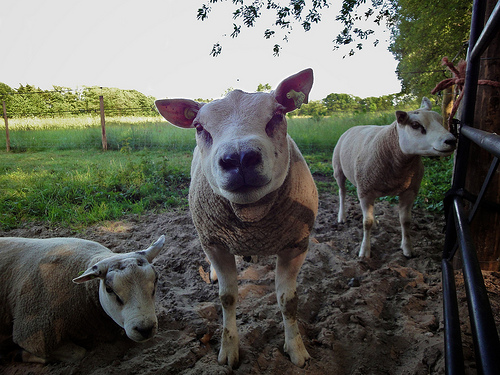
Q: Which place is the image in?
A: It is at the field.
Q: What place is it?
A: It is a field.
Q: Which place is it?
A: It is a field.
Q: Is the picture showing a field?
A: Yes, it is showing a field.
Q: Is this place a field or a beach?
A: It is a field.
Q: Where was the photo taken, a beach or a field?
A: It was taken at a field.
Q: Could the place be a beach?
A: No, it is a field.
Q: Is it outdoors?
A: Yes, it is outdoors.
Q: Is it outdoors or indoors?
A: It is outdoors.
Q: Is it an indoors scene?
A: No, it is outdoors.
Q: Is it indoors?
A: No, it is outdoors.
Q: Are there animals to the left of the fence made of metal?
A: Yes, there is an animal to the left of the fence.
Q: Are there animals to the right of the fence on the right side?
A: No, the animal is to the left of the fence.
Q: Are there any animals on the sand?
A: Yes, there is an animal on the sand.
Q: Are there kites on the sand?
A: No, there is an animal on the sand.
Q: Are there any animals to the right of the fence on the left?
A: Yes, there is an animal to the right of the fence.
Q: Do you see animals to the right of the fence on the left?
A: Yes, there is an animal to the right of the fence.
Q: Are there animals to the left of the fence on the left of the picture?
A: No, the animal is to the right of the fence.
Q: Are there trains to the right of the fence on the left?
A: No, there is an animal to the right of the fence.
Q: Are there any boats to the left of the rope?
A: No, there is an animal to the left of the rope.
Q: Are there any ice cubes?
A: No, there are no ice cubes.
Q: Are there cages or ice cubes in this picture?
A: No, there are no ice cubes or cages.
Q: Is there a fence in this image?
A: Yes, there is a fence.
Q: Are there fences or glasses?
A: Yes, there is a fence.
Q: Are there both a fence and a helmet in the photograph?
A: No, there is a fence but no helmets.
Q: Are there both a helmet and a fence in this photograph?
A: No, there is a fence but no helmets.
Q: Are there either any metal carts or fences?
A: Yes, there is a metal fence.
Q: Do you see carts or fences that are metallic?
A: Yes, the fence is metallic.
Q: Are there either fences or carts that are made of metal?
A: Yes, the fence is made of metal.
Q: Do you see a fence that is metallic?
A: Yes, there is a metal fence.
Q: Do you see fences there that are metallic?
A: Yes, there is a fence that is metallic.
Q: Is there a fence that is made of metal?
A: Yes, there is a fence that is made of metal.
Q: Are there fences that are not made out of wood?
A: Yes, there is a fence that is made of metal.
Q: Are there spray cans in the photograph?
A: No, there are no spray cans.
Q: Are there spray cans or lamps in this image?
A: No, there are no spray cans or lamps.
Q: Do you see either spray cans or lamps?
A: No, there are no spray cans or lamps.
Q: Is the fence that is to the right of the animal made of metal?
A: Yes, the fence is made of metal.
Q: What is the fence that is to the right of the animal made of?
A: The fence is made of metal.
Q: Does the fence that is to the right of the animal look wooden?
A: No, the fence is metallic.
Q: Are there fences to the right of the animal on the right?
A: Yes, there is a fence to the right of the animal.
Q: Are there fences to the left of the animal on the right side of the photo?
A: No, the fence is to the right of the animal.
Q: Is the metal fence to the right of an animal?
A: Yes, the fence is to the right of an animal.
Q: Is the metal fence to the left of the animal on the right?
A: No, the fence is to the right of the animal.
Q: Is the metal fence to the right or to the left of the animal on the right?
A: The fence is to the right of the animal.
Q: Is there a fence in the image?
A: Yes, there is a fence.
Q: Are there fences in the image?
A: Yes, there is a fence.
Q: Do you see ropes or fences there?
A: Yes, there is a fence.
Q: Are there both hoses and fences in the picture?
A: No, there is a fence but no hoses.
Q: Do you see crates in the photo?
A: No, there are no crates.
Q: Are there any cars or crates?
A: No, there are no crates or cars.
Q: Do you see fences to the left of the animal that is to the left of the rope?
A: Yes, there is a fence to the left of the animal.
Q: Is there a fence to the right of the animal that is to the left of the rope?
A: No, the fence is to the left of the animal.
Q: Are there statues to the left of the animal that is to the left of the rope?
A: No, there is a fence to the left of the animal.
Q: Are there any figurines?
A: No, there are no figurines.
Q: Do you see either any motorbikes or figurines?
A: No, there are no figurines or motorbikes.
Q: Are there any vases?
A: No, there are no vases.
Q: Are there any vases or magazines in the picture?
A: No, there are no vases or magazines.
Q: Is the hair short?
A: Yes, the hair is short.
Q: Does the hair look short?
A: Yes, the hair is short.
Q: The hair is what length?
A: The hair is short.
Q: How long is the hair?
A: The hair is short.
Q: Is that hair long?
A: No, the hair is short.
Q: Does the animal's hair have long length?
A: No, the hair is short.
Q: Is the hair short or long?
A: The hair is short.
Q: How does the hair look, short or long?
A: The hair is short.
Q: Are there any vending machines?
A: No, there are no vending machines.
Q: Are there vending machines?
A: No, there are no vending machines.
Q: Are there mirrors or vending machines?
A: No, there are no vending machines or mirrors.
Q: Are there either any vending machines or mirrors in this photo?
A: No, there are no vending machines or mirrors.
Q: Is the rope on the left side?
A: No, the rope is on the right of the image.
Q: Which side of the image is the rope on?
A: The rope is on the right of the image.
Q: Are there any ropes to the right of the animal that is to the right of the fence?
A: Yes, there is a rope to the right of the animal.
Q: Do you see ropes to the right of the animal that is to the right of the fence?
A: Yes, there is a rope to the right of the animal.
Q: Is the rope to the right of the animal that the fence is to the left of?
A: Yes, the rope is to the right of the animal.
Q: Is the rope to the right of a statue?
A: No, the rope is to the right of the animal.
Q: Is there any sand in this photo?
A: Yes, there is sand.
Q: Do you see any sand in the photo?
A: Yes, there is sand.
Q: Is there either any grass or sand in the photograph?
A: Yes, there is sand.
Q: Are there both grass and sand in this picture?
A: Yes, there are both sand and grass.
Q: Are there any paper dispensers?
A: No, there are no paper dispensers.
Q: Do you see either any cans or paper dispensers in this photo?
A: No, there are no paper dispensers or cans.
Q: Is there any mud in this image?
A: Yes, there is mud.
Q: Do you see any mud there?
A: Yes, there is mud.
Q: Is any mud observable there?
A: Yes, there is mud.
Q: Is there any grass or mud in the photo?
A: Yes, there is mud.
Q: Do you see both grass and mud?
A: Yes, there are both mud and grass.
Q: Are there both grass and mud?
A: Yes, there are both mud and grass.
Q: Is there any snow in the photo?
A: No, there is no snow.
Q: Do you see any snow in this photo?
A: No, there is no snow.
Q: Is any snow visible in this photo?
A: No, there is no snow.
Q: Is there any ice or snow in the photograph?
A: No, there are no snow or ice.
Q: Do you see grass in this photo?
A: Yes, there is grass.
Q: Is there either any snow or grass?
A: Yes, there is grass.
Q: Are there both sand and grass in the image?
A: Yes, there are both grass and sand.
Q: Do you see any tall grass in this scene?
A: Yes, there is tall grass.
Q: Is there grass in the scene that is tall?
A: Yes, there is grass that is tall.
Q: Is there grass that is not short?
A: Yes, there is tall grass.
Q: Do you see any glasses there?
A: No, there are no glasses.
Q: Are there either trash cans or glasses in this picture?
A: No, there are no glasses or trash cans.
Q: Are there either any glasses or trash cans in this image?
A: No, there are no glasses or trash cans.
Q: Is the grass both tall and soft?
A: Yes, the grass is tall and soft.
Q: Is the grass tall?
A: Yes, the grass is tall.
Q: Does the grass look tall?
A: Yes, the grass is tall.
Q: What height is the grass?
A: The grass is tall.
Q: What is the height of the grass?
A: The grass is tall.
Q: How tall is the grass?
A: The grass is tall.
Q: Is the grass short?
A: No, the grass is tall.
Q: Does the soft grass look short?
A: No, the grass is tall.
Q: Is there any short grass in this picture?
A: No, there is grass but it is tall.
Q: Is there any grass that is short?
A: No, there is grass but it is tall.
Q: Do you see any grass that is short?
A: No, there is grass but it is tall.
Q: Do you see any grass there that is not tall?
A: No, there is grass but it is tall.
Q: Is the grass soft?
A: Yes, the grass is soft.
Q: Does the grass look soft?
A: Yes, the grass is soft.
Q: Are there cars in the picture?
A: No, there are no cars.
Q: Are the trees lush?
A: Yes, the trees are lush.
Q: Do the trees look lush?
A: Yes, the trees are lush.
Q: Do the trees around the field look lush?
A: Yes, the trees are lush.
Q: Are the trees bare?
A: No, the trees are lush.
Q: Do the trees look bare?
A: No, the trees are lush.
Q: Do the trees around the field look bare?
A: No, the trees are lush.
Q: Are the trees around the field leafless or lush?
A: The trees are lush.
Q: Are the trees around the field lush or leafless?
A: The trees are lush.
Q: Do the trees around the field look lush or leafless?
A: The trees are lush.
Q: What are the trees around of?
A: The trees are around the field.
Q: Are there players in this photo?
A: No, there are no players.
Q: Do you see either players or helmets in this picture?
A: No, there are no players or helmets.